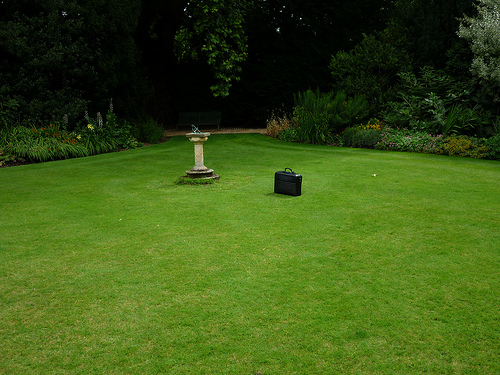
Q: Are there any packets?
A: No, there are no packets.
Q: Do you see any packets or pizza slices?
A: No, there are no packets or pizza slices.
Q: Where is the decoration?
A: The decoration is on the grass.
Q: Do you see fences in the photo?
A: No, there are no fences.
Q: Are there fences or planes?
A: No, there are no fences or planes.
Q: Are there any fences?
A: No, there are no fences.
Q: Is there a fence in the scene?
A: No, there are no fences.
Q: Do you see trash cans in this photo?
A: No, there are no trash cans.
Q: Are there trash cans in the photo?
A: No, there are no trash cans.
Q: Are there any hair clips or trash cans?
A: No, there are no trash cans or hair clips.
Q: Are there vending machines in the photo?
A: No, there are no vending machines.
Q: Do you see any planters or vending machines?
A: No, there are no vending machines or planters.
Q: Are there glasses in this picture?
A: No, there are no glasses.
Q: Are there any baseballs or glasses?
A: No, there are no glasses or baseballs.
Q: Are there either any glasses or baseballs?
A: No, there are no glasses or baseballs.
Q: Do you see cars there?
A: No, there are no cars.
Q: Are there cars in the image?
A: No, there are no cars.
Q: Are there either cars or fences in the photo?
A: No, there are no cars or fences.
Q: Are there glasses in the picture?
A: No, there are no glasses.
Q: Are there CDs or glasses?
A: No, there are no glasses or cds.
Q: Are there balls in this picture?
A: No, there are no balls.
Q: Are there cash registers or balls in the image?
A: No, there are no balls or cash registers.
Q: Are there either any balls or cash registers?
A: No, there are no balls or cash registers.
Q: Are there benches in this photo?
A: Yes, there is a bench.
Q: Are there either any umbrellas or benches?
A: Yes, there is a bench.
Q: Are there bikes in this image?
A: No, there are no bikes.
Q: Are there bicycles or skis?
A: No, there are no bicycles or skis.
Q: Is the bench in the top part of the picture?
A: Yes, the bench is in the top of the image.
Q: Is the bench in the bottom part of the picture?
A: No, the bench is in the top of the image.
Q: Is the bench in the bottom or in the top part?
A: The bench is in the top of the image.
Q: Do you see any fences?
A: No, there are no fences.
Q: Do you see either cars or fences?
A: No, there are no fences or cars.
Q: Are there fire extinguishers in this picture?
A: No, there are no fire extinguishers.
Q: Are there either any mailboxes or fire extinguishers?
A: No, there are no fire extinguishers or mailboxes.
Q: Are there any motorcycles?
A: No, there are no motorcycles.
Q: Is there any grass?
A: Yes, there is grass.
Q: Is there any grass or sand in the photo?
A: Yes, there is grass.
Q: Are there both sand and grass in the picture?
A: No, there is grass but no sand.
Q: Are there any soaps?
A: No, there are no soaps.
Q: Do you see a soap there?
A: No, there are no soaps.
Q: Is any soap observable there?
A: No, there are no soaps.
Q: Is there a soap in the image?
A: No, there are no soaps.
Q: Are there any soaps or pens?
A: No, there are no soaps or pens.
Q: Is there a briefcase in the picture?
A: Yes, there is a briefcase.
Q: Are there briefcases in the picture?
A: Yes, there is a briefcase.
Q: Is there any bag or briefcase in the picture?
A: Yes, there is a briefcase.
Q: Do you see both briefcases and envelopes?
A: No, there is a briefcase but no envelopes.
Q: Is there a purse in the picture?
A: No, there are no purses.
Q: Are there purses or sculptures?
A: No, there are no purses or sculptures.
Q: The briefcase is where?
A: The briefcase is on the grass.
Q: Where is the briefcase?
A: The briefcase is on the grass.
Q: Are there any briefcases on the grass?
A: Yes, there is a briefcase on the grass.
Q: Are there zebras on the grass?
A: No, there is a briefcase on the grass.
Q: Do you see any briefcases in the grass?
A: Yes, there is a briefcase in the grass.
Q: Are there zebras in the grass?
A: No, there is a briefcase in the grass.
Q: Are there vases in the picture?
A: No, there are no vases.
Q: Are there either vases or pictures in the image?
A: No, there are no vases or pictures.